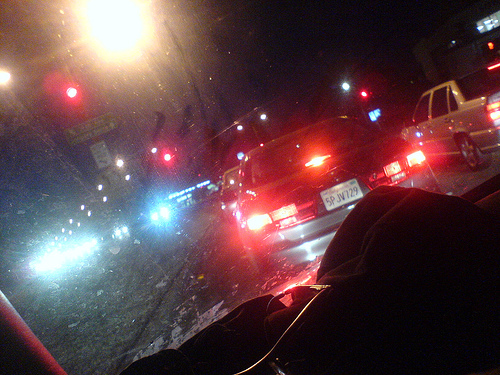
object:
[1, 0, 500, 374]
night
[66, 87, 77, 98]
light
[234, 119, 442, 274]
car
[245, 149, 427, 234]
brake lights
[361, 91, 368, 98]
street light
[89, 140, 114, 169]
sign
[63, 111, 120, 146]
letter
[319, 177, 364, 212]
license plate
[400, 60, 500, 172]
car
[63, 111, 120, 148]
sign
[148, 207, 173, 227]
headlights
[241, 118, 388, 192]
rear window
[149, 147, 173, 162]
traffic lights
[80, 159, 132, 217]
street lights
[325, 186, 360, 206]
letters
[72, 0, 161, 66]
street light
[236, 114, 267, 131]
lights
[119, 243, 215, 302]
road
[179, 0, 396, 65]
sky